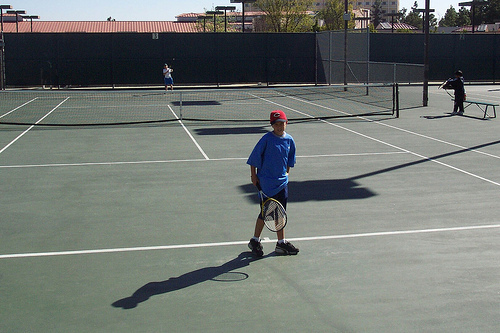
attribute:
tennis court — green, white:
[0, 78, 498, 330]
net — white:
[7, 87, 403, 128]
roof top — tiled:
[33, 12, 201, 31]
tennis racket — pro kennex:
[258, 183, 291, 231]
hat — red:
[266, 110, 292, 124]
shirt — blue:
[245, 132, 299, 197]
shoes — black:
[245, 238, 299, 258]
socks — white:
[250, 236, 291, 243]